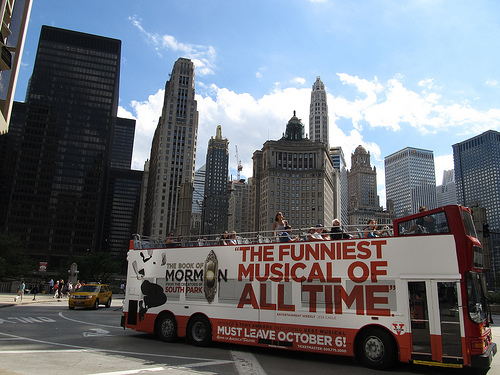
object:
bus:
[117, 197, 494, 374]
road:
[2, 286, 499, 374]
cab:
[68, 283, 113, 311]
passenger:
[164, 231, 178, 248]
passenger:
[177, 233, 187, 246]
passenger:
[218, 229, 230, 246]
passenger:
[229, 230, 239, 245]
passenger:
[272, 210, 290, 238]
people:
[14, 280, 26, 302]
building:
[0, 20, 147, 299]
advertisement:
[38, 261, 48, 272]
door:
[408, 280, 433, 355]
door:
[433, 278, 472, 364]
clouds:
[129, 62, 483, 163]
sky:
[26, 2, 497, 160]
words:
[236, 280, 259, 310]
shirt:
[275, 221, 289, 232]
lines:
[56, 309, 123, 333]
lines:
[4, 331, 237, 367]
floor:
[132, 225, 461, 247]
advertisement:
[141, 242, 399, 319]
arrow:
[82, 326, 117, 339]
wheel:
[153, 311, 180, 343]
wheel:
[184, 310, 214, 348]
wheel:
[352, 321, 400, 369]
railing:
[136, 221, 397, 241]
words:
[164, 286, 169, 293]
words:
[217, 325, 226, 335]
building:
[142, 49, 203, 250]